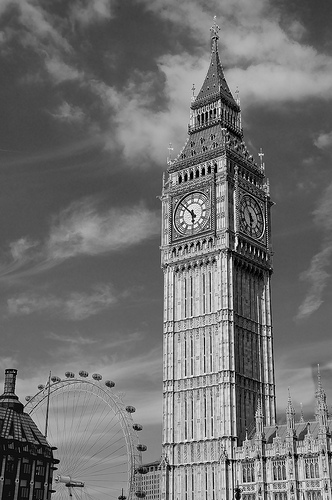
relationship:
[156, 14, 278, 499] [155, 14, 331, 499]
tower on a building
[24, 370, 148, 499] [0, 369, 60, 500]
ferris wheel behind a building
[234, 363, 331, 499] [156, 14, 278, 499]
building section to right of tower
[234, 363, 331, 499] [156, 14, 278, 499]
building section in front of tower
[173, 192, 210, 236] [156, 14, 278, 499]
clock on tower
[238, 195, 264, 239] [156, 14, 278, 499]
clock on tower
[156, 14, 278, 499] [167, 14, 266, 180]
tower has a roof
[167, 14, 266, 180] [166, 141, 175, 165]
roof has a decoration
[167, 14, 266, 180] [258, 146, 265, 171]
roof has a decoration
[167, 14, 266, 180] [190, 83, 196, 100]
roof has a decoration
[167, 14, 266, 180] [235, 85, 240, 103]
roof has a decoration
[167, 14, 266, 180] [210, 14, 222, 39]
roof has a decoration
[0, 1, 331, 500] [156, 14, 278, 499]
sky behind tower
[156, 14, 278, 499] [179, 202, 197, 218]
tower has a clock hand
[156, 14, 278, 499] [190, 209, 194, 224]
tower has a clock hand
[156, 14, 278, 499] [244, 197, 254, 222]
tower has a clock hand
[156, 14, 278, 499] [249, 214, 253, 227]
tower has a clock hand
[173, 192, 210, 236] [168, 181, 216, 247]
clock in a clock frame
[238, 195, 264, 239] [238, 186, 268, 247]
clock in a clock frame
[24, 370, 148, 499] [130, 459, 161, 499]
ferris wheel in front of a building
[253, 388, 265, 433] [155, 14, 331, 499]
steeple on a building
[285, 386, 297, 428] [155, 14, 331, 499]
steeple on a building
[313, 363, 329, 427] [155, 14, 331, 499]
steeple on a building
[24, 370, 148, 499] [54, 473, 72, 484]
ferris wheel has a center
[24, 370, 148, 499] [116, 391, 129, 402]
ferris wheel has an empty area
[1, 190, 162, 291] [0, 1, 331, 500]
cloud in sky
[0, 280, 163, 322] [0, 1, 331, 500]
cloud in sky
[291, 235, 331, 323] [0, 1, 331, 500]
cloud in sky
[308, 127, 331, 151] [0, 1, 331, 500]
cloud in sky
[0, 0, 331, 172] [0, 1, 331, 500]
cloud in sky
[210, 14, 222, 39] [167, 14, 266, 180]
decoration on top of roof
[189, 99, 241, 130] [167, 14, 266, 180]
balcony on roof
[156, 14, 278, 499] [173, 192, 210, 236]
tower has a clock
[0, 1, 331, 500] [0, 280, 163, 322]
sky has a cloud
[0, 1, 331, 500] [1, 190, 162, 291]
sky has a cloud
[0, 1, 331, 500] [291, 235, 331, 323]
sky has a cloud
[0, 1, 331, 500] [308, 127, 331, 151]
sky has a cloud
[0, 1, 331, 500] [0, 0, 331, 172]
sky has a cloud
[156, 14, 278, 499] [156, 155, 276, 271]
tower has a section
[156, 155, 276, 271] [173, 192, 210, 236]
section has a clock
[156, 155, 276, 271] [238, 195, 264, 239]
section has a clock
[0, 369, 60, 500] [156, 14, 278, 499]
building next to tower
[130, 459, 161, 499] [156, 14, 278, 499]
building next to tower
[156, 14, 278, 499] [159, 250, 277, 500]
tower has a base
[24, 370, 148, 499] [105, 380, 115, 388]
ferris wheel has a car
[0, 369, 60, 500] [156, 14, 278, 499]
building separate from tower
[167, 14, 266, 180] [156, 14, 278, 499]
roof on center of tower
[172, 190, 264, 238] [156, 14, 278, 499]
5:53 on tower